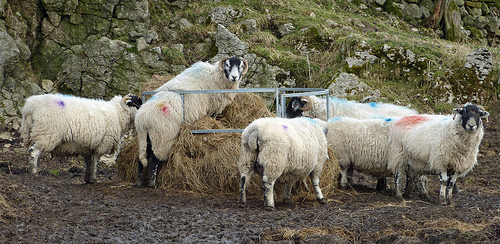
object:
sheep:
[19, 92, 143, 182]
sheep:
[131, 50, 250, 187]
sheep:
[236, 116, 329, 207]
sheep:
[386, 103, 492, 207]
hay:
[191, 159, 229, 188]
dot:
[51, 98, 67, 110]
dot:
[158, 103, 172, 117]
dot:
[395, 115, 431, 131]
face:
[217, 55, 249, 83]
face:
[453, 103, 491, 133]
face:
[286, 95, 307, 119]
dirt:
[66, 197, 96, 218]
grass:
[353, 23, 389, 45]